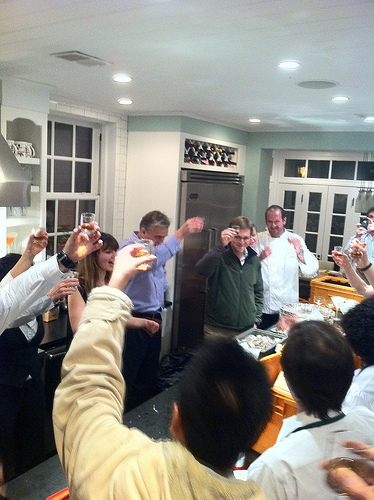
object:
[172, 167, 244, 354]
door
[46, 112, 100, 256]
window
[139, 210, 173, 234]
person's hair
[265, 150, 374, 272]
door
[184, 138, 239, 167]
wine rack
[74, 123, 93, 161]
pane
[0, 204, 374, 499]
people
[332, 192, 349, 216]
pane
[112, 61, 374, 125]
lights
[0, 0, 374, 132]
ceiling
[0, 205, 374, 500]
man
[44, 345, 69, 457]
dish washer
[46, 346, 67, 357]
handle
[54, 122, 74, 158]
pane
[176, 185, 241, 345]
refrigerator door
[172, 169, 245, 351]
refrigerator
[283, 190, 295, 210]
pane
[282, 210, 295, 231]
pane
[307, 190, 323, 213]
pane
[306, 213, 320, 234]
pane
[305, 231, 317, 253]
pane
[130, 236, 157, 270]
glass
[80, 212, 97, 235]
glass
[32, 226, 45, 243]
glass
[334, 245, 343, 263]
glass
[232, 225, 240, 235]
glass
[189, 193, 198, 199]
logo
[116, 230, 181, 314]
shirt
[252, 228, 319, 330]
outfit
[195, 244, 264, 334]
green jacket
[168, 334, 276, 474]
head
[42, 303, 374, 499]
table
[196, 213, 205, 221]
glass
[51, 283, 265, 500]
jacket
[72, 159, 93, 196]
pane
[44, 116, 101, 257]
door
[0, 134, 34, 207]
oven hood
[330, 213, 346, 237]
pane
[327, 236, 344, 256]
pane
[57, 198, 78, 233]
pane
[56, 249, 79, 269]
watch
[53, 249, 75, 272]
wrist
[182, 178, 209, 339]
pane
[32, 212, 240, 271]
glasses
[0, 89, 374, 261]
background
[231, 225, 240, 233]
glass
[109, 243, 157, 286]
hand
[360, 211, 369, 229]
cell phone